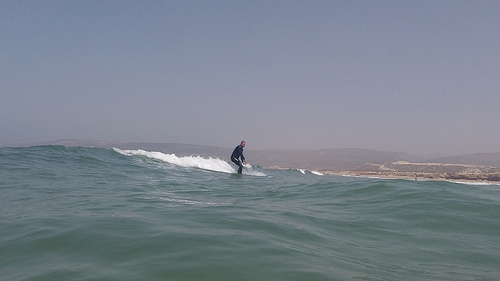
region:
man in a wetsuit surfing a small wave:
[223, 125, 260, 187]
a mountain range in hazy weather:
[243, 137, 497, 176]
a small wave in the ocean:
[0, 127, 230, 273]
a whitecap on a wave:
[105, 136, 237, 181]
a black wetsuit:
[228, 146, 248, 178]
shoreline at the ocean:
[306, 167, 496, 192]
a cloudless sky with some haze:
[23, 0, 495, 152]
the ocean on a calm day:
[0, 100, 494, 277]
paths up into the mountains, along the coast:
[345, 137, 497, 192]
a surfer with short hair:
[227, 137, 254, 196]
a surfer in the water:
[231, 139, 247, 176]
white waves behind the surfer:
[120, 145, 229, 170]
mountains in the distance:
[274, 141, 499, 176]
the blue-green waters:
[14, 173, 498, 272]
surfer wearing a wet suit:
[232, 140, 247, 174]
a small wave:
[37, 141, 232, 176]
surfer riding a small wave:
[130, 137, 316, 191]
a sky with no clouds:
[31, 25, 468, 130]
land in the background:
[328, 166, 494, 181]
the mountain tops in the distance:
[37, 135, 498, 165]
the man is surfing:
[225, 115, 281, 219]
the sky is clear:
[113, 49, 408, 134]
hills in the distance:
[282, 133, 441, 181]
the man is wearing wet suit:
[231, 144, 260, 181]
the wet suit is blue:
[215, 147, 253, 169]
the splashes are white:
[140, 132, 280, 207]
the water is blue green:
[165, 194, 442, 257]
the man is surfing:
[140, 97, 365, 236]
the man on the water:
[194, 147, 310, 213]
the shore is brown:
[331, 137, 484, 196]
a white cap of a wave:
[102, 137, 242, 177]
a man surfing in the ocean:
[222, 132, 277, 182]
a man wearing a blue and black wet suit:
[215, 137, 265, 190]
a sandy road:
[368, 154, 405, 181]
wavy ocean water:
[37, 128, 457, 279]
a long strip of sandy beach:
[311, 154, 498, 197]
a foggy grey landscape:
[44, 100, 156, 149]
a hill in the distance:
[411, 138, 459, 173]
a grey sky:
[144, 76, 325, 140]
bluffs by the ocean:
[49, 128, 122, 156]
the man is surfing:
[188, 107, 302, 206]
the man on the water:
[216, 124, 259, 201]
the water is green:
[152, 151, 360, 253]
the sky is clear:
[76, 18, 436, 189]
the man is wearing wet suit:
[215, 137, 274, 182]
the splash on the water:
[162, 121, 303, 198]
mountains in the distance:
[277, 130, 459, 165]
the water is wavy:
[72, 130, 337, 267]